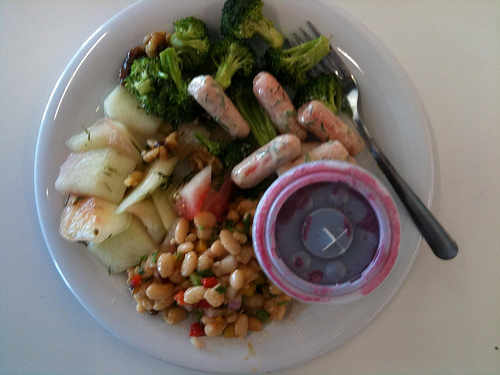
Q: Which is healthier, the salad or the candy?
A: The salad is healthier than the candy.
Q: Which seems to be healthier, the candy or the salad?
A: The salad is healthier than the candy.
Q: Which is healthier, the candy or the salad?
A: The salad is healthier than the candy.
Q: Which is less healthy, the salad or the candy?
A: The candy is less healthy than the salad.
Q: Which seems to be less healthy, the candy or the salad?
A: The candy is less healthy than the salad.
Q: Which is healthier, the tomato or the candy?
A: The tomato is healthier than the candy.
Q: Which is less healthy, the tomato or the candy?
A: The candy is less healthy than the tomato.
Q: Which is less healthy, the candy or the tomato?
A: The candy is less healthy than the tomato.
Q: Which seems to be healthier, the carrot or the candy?
A: The carrot is healthier than the candy.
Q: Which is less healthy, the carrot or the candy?
A: The candy is less healthy than the carrot.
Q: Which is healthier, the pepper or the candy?
A: The pepper is healthier than the candy.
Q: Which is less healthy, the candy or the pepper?
A: The candy is less healthy than the pepper.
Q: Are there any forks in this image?
A: Yes, there is a fork.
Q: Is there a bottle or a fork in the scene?
A: Yes, there is a fork.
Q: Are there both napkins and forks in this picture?
A: No, there is a fork but no napkins.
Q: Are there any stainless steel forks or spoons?
A: Yes, there is a stainless steel fork.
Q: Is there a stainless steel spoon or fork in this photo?
A: Yes, there is a stainless steel fork.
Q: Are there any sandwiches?
A: No, there are no sandwiches.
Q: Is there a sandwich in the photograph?
A: No, there are no sandwiches.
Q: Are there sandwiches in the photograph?
A: No, there are no sandwiches.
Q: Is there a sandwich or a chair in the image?
A: No, there are no sandwiches or chairs.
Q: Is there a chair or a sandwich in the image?
A: No, there are no sandwiches or chairs.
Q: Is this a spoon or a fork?
A: This is a fork.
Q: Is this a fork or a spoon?
A: This is a fork.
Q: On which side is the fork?
A: The fork is on the right of the image.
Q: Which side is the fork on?
A: The fork is on the right of the image.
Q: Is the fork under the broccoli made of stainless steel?
A: Yes, the fork is made of stainless steel.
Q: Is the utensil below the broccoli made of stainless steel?
A: Yes, the fork is made of stainless steel.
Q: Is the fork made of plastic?
A: No, the fork is made of stainless steel.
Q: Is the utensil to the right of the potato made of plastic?
A: No, the fork is made of stainless steel.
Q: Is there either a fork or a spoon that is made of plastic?
A: No, there is a fork but it is made of stainless steel.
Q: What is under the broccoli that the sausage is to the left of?
A: The fork is under the broccoli.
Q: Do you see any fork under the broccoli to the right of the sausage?
A: Yes, there is a fork under the broccoli.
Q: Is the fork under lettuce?
A: No, the fork is under the broccoli.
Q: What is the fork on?
A: The fork is on the plate.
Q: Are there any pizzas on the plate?
A: No, there is a fork on the plate.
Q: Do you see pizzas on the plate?
A: No, there is a fork on the plate.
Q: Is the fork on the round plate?
A: Yes, the fork is on the plate.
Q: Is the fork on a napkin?
A: No, the fork is on the plate.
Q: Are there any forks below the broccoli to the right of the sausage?
A: Yes, there is a fork below the broccoli.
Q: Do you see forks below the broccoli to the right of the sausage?
A: Yes, there is a fork below the broccoli.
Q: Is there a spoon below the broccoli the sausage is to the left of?
A: No, there is a fork below the broccoli.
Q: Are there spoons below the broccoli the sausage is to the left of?
A: No, there is a fork below the broccoli.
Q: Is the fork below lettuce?
A: No, the fork is below the broccoli.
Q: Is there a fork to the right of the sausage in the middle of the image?
A: Yes, there is a fork to the right of the sausage.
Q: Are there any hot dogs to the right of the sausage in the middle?
A: No, there is a fork to the right of the sausage.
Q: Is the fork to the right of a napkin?
A: No, the fork is to the right of a sausage.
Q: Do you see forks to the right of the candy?
A: Yes, there is a fork to the right of the candy.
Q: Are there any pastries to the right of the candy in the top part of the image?
A: No, there is a fork to the right of the candy.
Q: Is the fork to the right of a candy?
A: Yes, the fork is to the right of a candy.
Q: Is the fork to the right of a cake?
A: No, the fork is to the right of a candy.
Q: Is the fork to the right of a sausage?
A: Yes, the fork is to the right of a sausage.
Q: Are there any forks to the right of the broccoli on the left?
A: Yes, there is a fork to the right of the broccoli.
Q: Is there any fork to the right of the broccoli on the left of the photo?
A: Yes, there is a fork to the right of the broccoli.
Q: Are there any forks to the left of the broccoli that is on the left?
A: No, the fork is to the right of the broccoli.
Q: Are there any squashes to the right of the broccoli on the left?
A: No, there is a fork to the right of the broccoli.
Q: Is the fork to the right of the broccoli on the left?
A: Yes, the fork is to the right of the broccoli.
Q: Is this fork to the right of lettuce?
A: No, the fork is to the right of the broccoli.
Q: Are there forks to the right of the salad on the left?
A: Yes, there is a fork to the right of the salad.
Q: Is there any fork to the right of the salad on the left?
A: Yes, there is a fork to the right of the salad.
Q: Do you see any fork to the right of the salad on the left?
A: Yes, there is a fork to the right of the salad.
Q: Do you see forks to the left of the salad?
A: No, the fork is to the right of the salad.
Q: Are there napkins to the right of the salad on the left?
A: No, there is a fork to the right of the salad.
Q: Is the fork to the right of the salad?
A: Yes, the fork is to the right of the salad.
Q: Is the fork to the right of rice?
A: No, the fork is to the right of the salad.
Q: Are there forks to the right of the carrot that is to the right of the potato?
A: Yes, there is a fork to the right of the carrot.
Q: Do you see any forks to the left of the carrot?
A: No, the fork is to the right of the carrot.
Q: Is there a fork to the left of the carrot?
A: No, the fork is to the right of the carrot.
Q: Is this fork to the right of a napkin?
A: No, the fork is to the right of a carrot.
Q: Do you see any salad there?
A: Yes, there is salad.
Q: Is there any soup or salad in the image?
A: Yes, there is salad.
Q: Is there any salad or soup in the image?
A: Yes, there is salad.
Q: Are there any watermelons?
A: No, there are no watermelons.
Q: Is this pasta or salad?
A: This is salad.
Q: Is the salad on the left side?
A: Yes, the salad is on the left of the image.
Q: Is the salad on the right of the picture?
A: No, the salad is on the left of the image.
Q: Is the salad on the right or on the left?
A: The salad is on the left of the image.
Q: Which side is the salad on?
A: The salad is on the left of the image.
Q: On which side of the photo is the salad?
A: The salad is on the left of the image.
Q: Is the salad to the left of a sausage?
A: Yes, the salad is to the left of a sausage.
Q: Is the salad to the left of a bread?
A: No, the salad is to the left of a sausage.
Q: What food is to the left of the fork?
A: The food is salad.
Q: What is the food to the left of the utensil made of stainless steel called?
A: The food is salad.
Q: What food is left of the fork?
A: The food is salad.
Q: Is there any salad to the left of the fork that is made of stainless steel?
A: Yes, there is salad to the left of the fork.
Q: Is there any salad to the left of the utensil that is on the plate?
A: Yes, there is salad to the left of the fork.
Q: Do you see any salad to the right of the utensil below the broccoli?
A: No, the salad is to the left of the fork.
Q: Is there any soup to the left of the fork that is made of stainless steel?
A: No, there is salad to the left of the fork.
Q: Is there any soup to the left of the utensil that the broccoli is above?
A: No, there is salad to the left of the fork.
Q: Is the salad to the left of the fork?
A: Yes, the salad is to the left of the fork.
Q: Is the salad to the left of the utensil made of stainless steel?
A: Yes, the salad is to the left of the fork.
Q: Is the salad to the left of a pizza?
A: No, the salad is to the left of the fork.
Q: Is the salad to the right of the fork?
A: No, the salad is to the left of the fork.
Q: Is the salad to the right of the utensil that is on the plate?
A: No, the salad is to the left of the fork.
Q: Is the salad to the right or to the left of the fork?
A: The salad is to the left of the fork.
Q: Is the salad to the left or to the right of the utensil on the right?
A: The salad is to the left of the fork.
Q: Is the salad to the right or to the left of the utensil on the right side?
A: The salad is to the left of the fork.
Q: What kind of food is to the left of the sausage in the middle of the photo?
A: The food is salad.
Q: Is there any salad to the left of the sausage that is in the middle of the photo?
A: Yes, there is salad to the left of the sausage.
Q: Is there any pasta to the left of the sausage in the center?
A: No, there is salad to the left of the sausage.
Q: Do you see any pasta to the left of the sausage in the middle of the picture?
A: No, there is salad to the left of the sausage.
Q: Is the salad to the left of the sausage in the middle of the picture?
A: Yes, the salad is to the left of the sausage.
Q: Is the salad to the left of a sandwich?
A: No, the salad is to the left of the sausage.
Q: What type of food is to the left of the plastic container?
A: The food is salad.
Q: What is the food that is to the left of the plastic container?
A: The food is salad.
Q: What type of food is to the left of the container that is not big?
A: The food is salad.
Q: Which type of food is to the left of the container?
A: The food is salad.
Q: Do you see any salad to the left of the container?
A: Yes, there is salad to the left of the container.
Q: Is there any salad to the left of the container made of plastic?
A: Yes, there is salad to the left of the container.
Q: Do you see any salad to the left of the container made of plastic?
A: Yes, there is salad to the left of the container.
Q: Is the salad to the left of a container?
A: Yes, the salad is to the left of a container.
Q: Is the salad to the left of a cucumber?
A: No, the salad is to the left of a container.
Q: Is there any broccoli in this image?
A: Yes, there is broccoli.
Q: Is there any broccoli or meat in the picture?
A: Yes, there is broccoli.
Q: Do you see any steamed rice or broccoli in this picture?
A: Yes, there is steamed broccoli.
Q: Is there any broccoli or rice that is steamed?
A: Yes, the broccoli is steamed.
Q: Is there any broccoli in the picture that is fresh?
A: Yes, there is fresh broccoli.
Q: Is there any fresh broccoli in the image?
A: Yes, there is fresh broccoli.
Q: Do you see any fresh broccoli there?
A: Yes, there is fresh broccoli.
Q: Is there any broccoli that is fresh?
A: Yes, there is broccoli that is fresh.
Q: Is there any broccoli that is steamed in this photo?
A: Yes, there is steamed broccoli.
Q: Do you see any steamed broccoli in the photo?
A: Yes, there is steamed broccoli.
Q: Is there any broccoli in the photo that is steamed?
A: Yes, there is broccoli that is steamed.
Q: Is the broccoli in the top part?
A: Yes, the broccoli is in the top of the image.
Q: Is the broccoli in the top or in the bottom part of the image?
A: The broccoli is in the top of the image.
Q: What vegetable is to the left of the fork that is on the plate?
A: The vegetable is broccoli.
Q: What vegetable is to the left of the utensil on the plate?
A: The vegetable is broccoli.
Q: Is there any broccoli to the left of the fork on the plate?
A: Yes, there is broccoli to the left of the fork.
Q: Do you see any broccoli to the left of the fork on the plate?
A: Yes, there is broccoli to the left of the fork.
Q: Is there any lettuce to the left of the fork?
A: No, there is broccoli to the left of the fork.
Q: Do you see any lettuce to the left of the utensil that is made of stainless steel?
A: No, there is broccoli to the left of the fork.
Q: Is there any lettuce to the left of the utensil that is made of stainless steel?
A: No, there is broccoli to the left of the fork.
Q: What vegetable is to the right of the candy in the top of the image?
A: The vegetable is broccoli.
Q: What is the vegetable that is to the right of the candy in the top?
A: The vegetable is broccoli.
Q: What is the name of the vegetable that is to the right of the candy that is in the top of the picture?
A: The vegetable is broccoli.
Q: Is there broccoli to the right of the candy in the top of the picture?
A: Yes, there is broccoli to the right of the candy.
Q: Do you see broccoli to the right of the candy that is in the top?
A: Yes, there is broccoli to the right of the candy.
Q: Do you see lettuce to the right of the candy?
A: No, there is broccoli to the right of the candy.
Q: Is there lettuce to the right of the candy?
A: No, there is broccoli to the right of the candy.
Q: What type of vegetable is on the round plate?
A: The vegetable is broccoli.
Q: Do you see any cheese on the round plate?
A: No, there is broccoli on the plate.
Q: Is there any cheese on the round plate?
A: No, there is broccoli on the plate.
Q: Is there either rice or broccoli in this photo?
A: Yes, there is broccoli.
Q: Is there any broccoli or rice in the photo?
A: Yes, there is broccoli.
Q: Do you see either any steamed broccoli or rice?
A: Yes, there is steamed broccoli.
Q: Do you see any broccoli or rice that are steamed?
A: Yes, the broccoli is steamed.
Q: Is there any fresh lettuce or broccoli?
A: Yes, there is fresh broccoli.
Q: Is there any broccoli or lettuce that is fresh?
A: Yes, the broccoli is fresh.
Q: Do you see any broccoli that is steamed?
A: Yes, there is steamed broccoli.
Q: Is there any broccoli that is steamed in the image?
A: Yes, there is steamed broccoli.